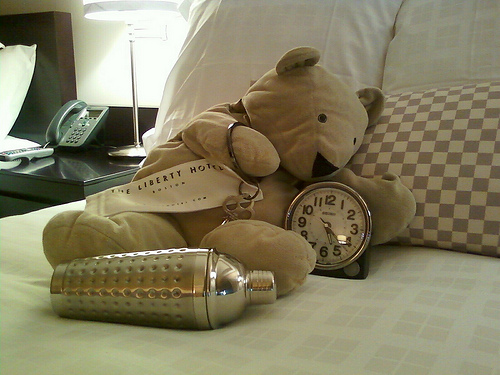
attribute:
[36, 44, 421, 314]
doll — eye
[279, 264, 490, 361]
sheet — white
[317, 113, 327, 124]
dot — small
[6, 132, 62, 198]
tv remote — television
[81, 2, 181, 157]
white lamp — bright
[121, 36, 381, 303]
bear — teddy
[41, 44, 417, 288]
creamteddy — cream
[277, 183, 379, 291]
clock — small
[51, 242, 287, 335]
bottle — mouth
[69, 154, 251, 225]
label — the liberty hotel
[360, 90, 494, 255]
pillow — checkered, patterned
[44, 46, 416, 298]
bear — cute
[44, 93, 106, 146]
telephone system — elevated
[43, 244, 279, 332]
drink shaker — metal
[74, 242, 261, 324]
bottle — water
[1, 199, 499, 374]
hotel bed — relaxing, comfortable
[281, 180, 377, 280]
clock — small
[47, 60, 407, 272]
bear — teddy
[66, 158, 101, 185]
table — end, black